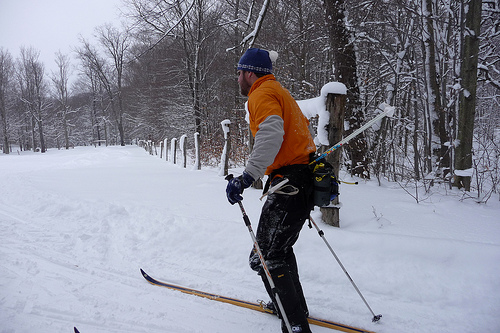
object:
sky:
[0, 1, 255, 108]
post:
[315, 82, 351, 228]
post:
[191, 131, 203, 172]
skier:
[186, 45, 370, 332]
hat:
[238, 48, 273, 77]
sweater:
[245, 77, 315, 174]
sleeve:
[242, 117, 285, 181]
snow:
[322, 80, 344, 96]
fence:
[135, 88, 347, 227]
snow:
[112, 148, 469, 313]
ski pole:
[221, 172, 300, 333]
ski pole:
[304, 210, 385, 323]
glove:
[226, 175, 254, 205]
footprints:
[124, 214, 207, 283]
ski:
[139, 261, 367, 333]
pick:
[322, 101, 407, 159]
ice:
[377, 102, 395, 123]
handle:
[259, 177, 293, 201]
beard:
[239, 74, 251, 96]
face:
[236, 65, 249, 95]